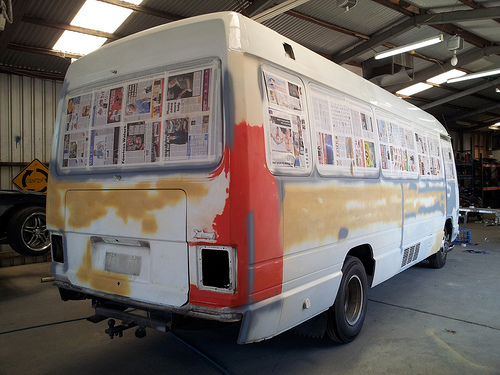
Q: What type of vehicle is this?
A: A van.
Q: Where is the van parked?
A: In a garage.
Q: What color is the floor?
A: Dark gray.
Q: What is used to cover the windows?
A: Newspapers.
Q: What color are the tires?
A: Black.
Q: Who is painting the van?
A: Nobody.